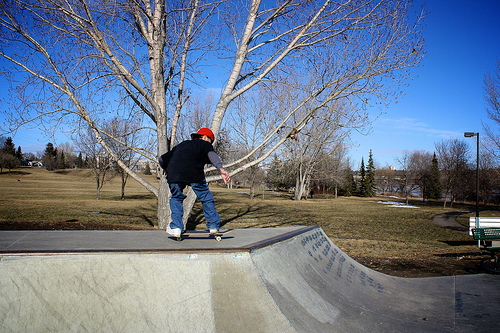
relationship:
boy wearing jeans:
[154, 124, 234, 236] [153, 168, 229, 247]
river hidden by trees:
[363, 178, 467, 204] [342, 146, 456, 206]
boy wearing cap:
[140, 122, 244, 238] [189, 123, 215, 140]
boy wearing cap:
[154, 124, 234, 236] [190, 128, 216, 142]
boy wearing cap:
[154, 124, 234, 236] [185, 125, 219, 142]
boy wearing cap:
[154, 124, 234, 236] [190, 125, 220, 141]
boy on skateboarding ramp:
[154, 124, 234, 236] [16, 229, 469, 329]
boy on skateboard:
[154, 124, 234, 236] [161, 225, 239, 241]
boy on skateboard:
[154, 124, 234, 236] [168, 229, 236, 243]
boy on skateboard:
[154, 124, 234, 236] [165, 229, 230, 241]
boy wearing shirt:
[154, 124, 234, 236] [158, 139, 228, 191]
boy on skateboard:
[154, 124, 234, 236] [165, 225, 236, 245]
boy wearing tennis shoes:
[154, 124, 234, 236] [163, 222, 223, 240]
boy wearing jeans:
[154, 124, 234, 236] [162, 182, 217, 232]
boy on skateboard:
[154, 124, 234, 236] [158, 230, 231, 242]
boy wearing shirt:
[154, 124, 234, 236] [152, 138, 235, 193]